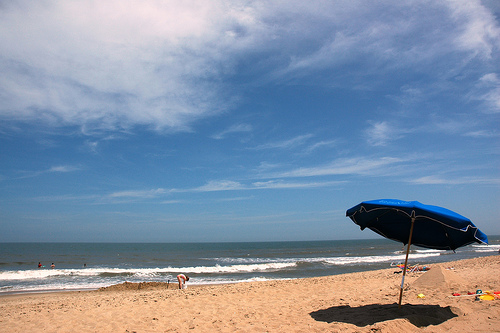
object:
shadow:
[307, 302, 459, 328]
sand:
[274, 311, 327, 333]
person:
[177, 274, 190, 290]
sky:
[0, 0, 499, 244]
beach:
[0, 254, 500, 332]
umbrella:
[345, 198, 486, 311]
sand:
[223, 295, 299, 320]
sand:
[169, 293, 269, 318]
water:
[0, 235, 500, 295]